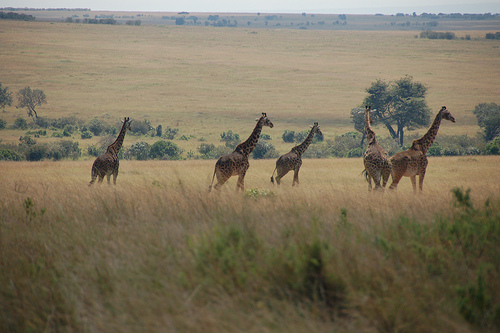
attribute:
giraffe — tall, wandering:
[91, 118, 135, 183]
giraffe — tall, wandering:
[214, 110, 273, 188]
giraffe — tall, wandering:
[271, 121, 323, 187]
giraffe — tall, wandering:
[363, 104, 393, 188]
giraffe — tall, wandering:
[389, 105, 455, 190]